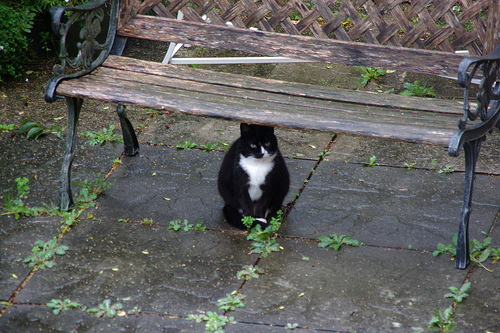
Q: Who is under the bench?
A: Cat.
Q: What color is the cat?
A: Black.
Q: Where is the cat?
A: Under the bench.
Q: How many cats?
A: 1.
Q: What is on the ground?
A: The cat.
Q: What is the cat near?
A: Weeds.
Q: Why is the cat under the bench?
A: Cover.